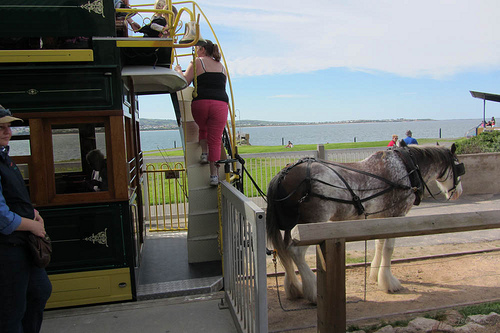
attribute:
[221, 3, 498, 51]
clouds — white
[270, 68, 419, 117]
sky — blue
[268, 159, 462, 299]
horse — white, brown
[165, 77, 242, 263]
stairs — curved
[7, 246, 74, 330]
pants — black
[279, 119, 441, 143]
water — calm, blue, in background, in distance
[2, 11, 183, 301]
building — yellow, brown, red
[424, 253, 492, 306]
dirt — brown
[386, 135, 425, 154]
people — in background, in distance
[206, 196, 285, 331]
fence — metal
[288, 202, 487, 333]
fence — wooden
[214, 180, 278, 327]
gate — metal, grey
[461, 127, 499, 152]
bushes — green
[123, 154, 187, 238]
gate — yellow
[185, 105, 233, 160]
pants — pink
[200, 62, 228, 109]
shirt — black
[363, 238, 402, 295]
feet — white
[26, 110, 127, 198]
window — wooden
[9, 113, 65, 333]
person — in fore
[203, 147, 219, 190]
shoes — white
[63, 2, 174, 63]
people — sitting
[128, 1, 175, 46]
woman — sitting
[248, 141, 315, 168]
rail — silver